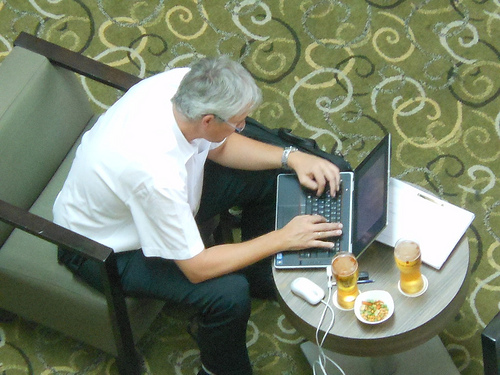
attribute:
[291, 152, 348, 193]
hand —  The right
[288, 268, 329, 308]
mouse — white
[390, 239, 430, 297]
glass — full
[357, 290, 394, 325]
bowl — white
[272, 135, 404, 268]
laptop — silver and black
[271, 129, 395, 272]
laptop — black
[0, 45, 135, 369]
grey chair — gray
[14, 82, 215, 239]
shirt — white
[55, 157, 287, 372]
jeans — navy blue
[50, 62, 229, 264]
shirt — white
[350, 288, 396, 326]
bowl — small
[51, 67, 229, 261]
tee shirt — white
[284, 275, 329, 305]
mouse —  white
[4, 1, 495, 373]
design — swirly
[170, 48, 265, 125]
hair — gray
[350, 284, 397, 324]
bowl — white, small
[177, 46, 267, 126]
hair — gray